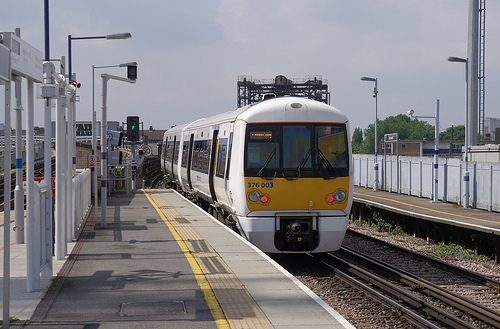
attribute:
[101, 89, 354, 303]
train — yellow, white, passenger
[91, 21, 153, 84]
lighting — outdoors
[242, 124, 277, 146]
sign — electronic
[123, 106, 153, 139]
light — green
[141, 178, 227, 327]
line — yellow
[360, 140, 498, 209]
wall — gray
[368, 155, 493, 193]
fence — grey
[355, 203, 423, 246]
weeds — growing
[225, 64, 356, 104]
structure — black, tall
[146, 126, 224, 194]
doors — open